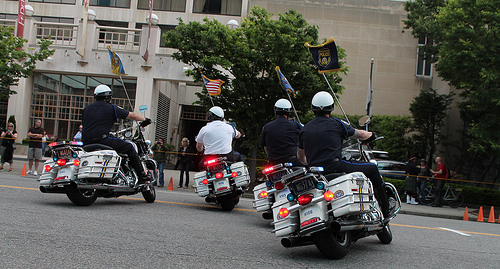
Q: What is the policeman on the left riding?
A: A motorcyle.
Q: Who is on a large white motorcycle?
A: Police man.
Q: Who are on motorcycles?
A: Police officers.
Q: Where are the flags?
A: Police motorcycles.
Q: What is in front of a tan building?
A: A bush.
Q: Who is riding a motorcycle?
A: A policeman.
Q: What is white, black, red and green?
A: A motorcycle.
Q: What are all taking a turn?
A: Motorcycles.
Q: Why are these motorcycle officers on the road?
A: A parade is about to start.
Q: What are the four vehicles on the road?
A: Police motorcycles.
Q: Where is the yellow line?
A: In back of the police in bikes.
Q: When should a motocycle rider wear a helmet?
A: Whenever riding a motocycle.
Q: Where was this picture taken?
A: On a city street.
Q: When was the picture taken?
A: Daytime.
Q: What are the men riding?
A: Motorcycles.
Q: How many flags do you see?
A: 8.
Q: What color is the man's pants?
A: Black.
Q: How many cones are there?
A: 5.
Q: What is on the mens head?
A: Helmets.